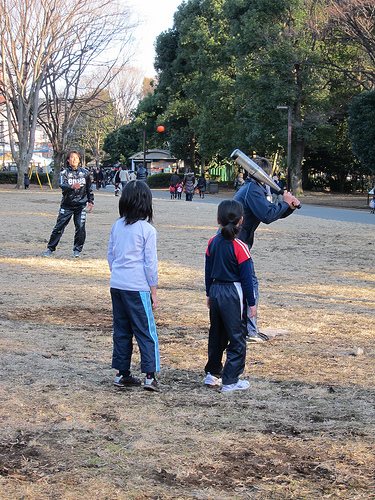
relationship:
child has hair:
[108, 176, 163, 393] [112, 175, 158, 219]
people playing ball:
[230, 156, 302, 249] [157, 125, 165, 133]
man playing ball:
[46, 150, 97, 257] [157, 125, 165, 133]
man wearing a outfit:
[36, 142, 105, 255] [36, 155, 100, 266]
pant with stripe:
[110, 286, 160, 376] [139, 288, 160, 371]